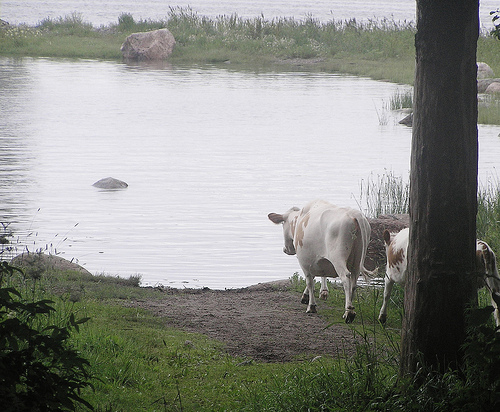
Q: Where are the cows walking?
A: Toward the water.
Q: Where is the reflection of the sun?
A: On the water.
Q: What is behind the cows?
A: A tree trunk.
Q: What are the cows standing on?
A: Grass and dirt.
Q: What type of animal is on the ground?
A: Cows.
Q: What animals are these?
A: Cows.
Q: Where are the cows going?
A: To the water.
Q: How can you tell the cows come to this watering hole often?
A: They have trampled a trail.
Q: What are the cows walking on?
A: Muddy trail.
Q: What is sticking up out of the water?
A: Rock.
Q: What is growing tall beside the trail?
A: A tree.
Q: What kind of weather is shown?
A: Overcast cloudy.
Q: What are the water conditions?
A: Slightly rippled.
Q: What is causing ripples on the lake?
A: Wind.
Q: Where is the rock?
A: In water.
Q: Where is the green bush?
A: By water.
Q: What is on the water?
A: Ripples.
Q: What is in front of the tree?
A: Cows.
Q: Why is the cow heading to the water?
A: To drink.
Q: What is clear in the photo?
A: The lake.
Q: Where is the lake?
A: In front of the cows.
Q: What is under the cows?
A: Dirt.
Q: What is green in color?
A: Grass.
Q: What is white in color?
A: The cow.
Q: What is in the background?
A: Grass.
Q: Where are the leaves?
A: On a tree.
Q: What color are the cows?
A: White and brown.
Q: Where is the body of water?
A: In front of the cows.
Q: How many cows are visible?
A: Two.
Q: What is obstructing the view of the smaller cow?
A: A tree trunk.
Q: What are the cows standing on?
A: A dirt path.